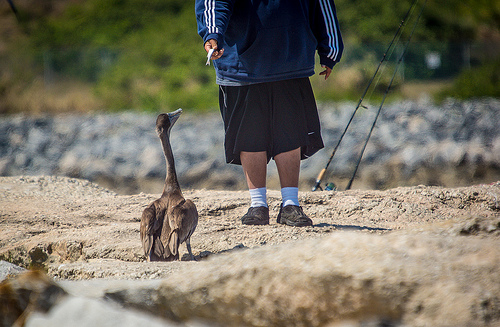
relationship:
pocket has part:
[218, 87, 226, 111] [222, 103, 229, 107]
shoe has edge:
[242, 206, 269, 227] [266, 211, 270, 226]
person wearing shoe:
[196, 1, 344, 226] [242, 206, 269, 227]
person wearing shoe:
[196, 1, 344, 226] [278, 205, 314, 226]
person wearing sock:
[196, 1, 344, 226] [281, 187, 298, 208]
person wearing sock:
[196, 1, 344, 226] [250, 187, 270, 206]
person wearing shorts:
[196, 1, 344, 226] [216, 81, 326, 166]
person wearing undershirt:
[196, 1, 344, 226] [215, 74, 315, 87]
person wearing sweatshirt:
[196, 1, 344, 226] [196, 1, 343, 83]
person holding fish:
[196, 1, 344, 226] [207, 49, 213, 68]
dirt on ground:
[428, 200, 441, 211] [1, 0, 497, 327]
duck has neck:
[140, 109, 198, 263] [162, 142, 181, 193]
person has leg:
[196, 1, 344, 226] [275, 148, 312, 228]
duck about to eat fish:
[140, 109, 198, 263] [207, 49, 213, 68]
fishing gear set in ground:
[346, 7, 426, 193] [1, 0, 497, 327]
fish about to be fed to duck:
[207, 49, 213, 68] [140, 109, 198, 263]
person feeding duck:
[196, 1, 344, 226] [140, 109, 198, 263]